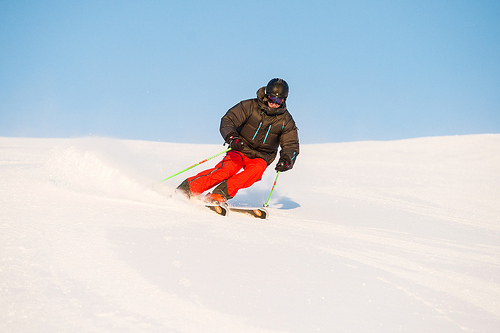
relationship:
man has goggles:
[175, 77, 302, 206] [265, 93, 287, 105]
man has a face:
[175, 77, 302, 206] [267, 92, 283, 113]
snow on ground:
[1, 138, 499, 332] [2, 138, 496, 332]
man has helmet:
[175, 77, 302, 206] [264, 78, 290, 105]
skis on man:
[202, 204, 268, 222] [175, 77, 302, 206]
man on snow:
[175, 77, 302, 206] [1, 138, 499, 332]